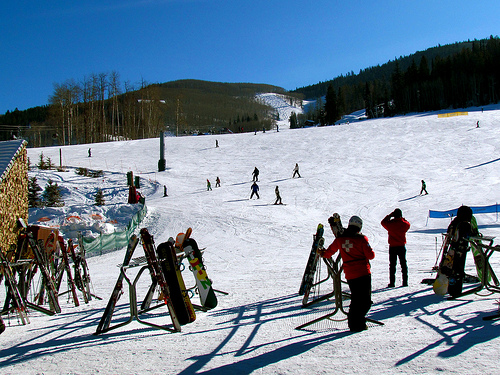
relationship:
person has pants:
[317, 214, 376, 333] [343, 272, 373, 332]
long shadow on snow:
[175, 292, 354, 373] [6, 94, 500, 375]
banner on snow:
[426, 203, 498, 230] [6, 94, 500, 375]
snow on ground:
[6, 94, 500, 375] [1, 105, 490, 369]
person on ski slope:
[416, 179, 429, 197] [12, 110, 500, 372]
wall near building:
[74, 203, 154, 265] [1, 129, 35, 275]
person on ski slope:
[380, 207, 412, 290] [327, 240, 494, 372]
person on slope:
[270, 184, 287, 209] [267, 119, 362, 162]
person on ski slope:
[249, 181, 260, 199] [0, 111, 497, 373]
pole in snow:
[150, 127, 167, 173] [97, 341, 175, 363]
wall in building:
[3, 166, 24, 233] [5, 133, 47, 293]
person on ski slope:
[473, 119, 480, 129] [153, 104, 499, 373]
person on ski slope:
[291, 160, 302, 178] [153, 104, 499, 373]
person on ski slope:
[416, 179, 429, 197] [153, 104, 499, 373]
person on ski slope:
[273, 185, 283, 206] [153, 104, 499, 373]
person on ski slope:
[249, 181, 260, 201] [153, 104, 499, 373]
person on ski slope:
[251, 166, 260, 182] [153, 104, 499, 373]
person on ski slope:
[214, 177, 221, 188] [153, 104, 499, 373]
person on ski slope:
[202, 178, 214, 192] [153, 104, 499, 373]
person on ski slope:
[213, 138, 220, 146] [153, 104, 499, 373]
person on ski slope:
[85, 146, 92, 156] [153, 104, 499, 373]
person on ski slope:
[380, 208, 412, 290] [153, 104, 499, 373]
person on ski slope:
[317, 215, 377, 333] [153, 104, 499, 373]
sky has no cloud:
[1, 1, 496, 121] [0, 1, 499, 92]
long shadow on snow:
[191, 329, 364, 375] [190, 330, 349, 347]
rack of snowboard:
[91, 228, 230, 338] [183, 238, 220, 309]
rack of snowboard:
[91, 228, 230, 338] [154, 242, 195, 324]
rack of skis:
[91, 228, 230, 338] [94, 232, 139, 337]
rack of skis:
[91, 228, 230, 338] [138, 222, 180, 340]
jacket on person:
[379, 216, 414, 246] [317, 215, 377, 333]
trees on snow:
[47, 72, 167, 138] [6, 94, 500, 375]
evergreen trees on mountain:
[265, 31, 498, 119] [318, 46, 482, 108]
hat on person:
[345, 212, 365, 233] [317, 215, 377, 333]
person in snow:
[317, 215, 377, 333] [238, 135, 351, 371]